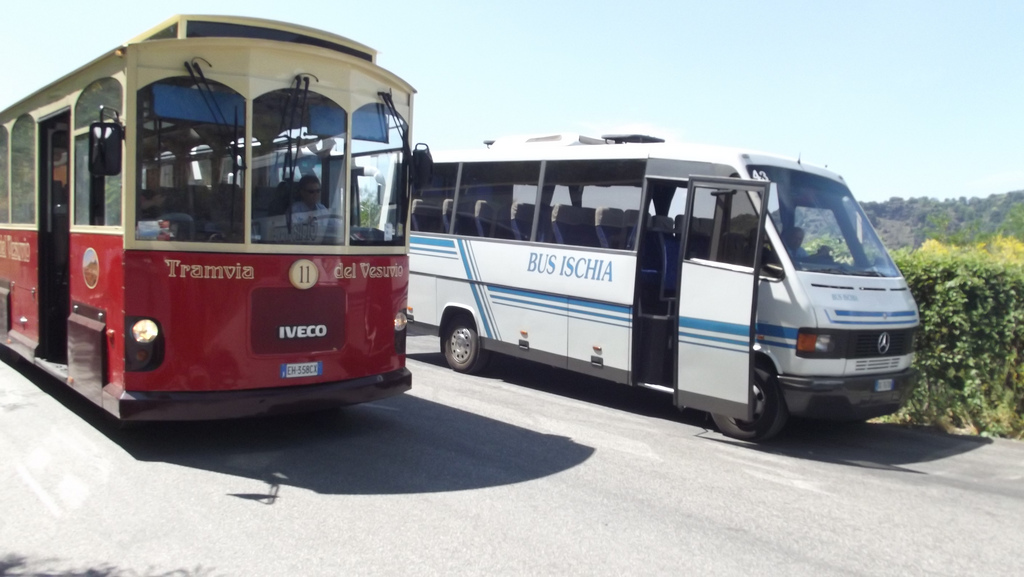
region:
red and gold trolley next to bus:
[0, 16, 419, 427]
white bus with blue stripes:
[400, 129, 926, 440]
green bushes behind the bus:
[891, 240, 1022, 431]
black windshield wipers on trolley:
[174, 60, 409, 237]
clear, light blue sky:
[0, 0, 1019, 197]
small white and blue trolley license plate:
[276, 356, 322, 377]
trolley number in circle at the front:
[289, 257, 321, 287]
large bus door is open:
[627, 172, 771, 410]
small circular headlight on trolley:
[128, 318, 155, 345]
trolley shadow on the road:
[136, 386, 593, 507]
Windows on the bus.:
[408, 43, 842, 436]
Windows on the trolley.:
[44, 36, 498, 400]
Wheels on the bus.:
[423, 276, 664, 469]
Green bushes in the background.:
[729, 119, 1008, 462]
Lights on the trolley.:
[50, 168, 342, 464]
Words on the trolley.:
[119, 219, 222, 350]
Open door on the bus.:
[616, 122, 826, 490]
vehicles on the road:
[40, 13, 957, 565]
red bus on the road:
[36, 0, 492, 464]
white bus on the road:
[451, 69, 1005, 421]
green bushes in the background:
[802, 168, 993, 396]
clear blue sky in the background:
[416, 10, 1021, 198]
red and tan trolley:
[37, 17, 423, 442]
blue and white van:
[463, 103, 865, 416]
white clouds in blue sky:
[472, 47, 536, 104]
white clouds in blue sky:
[698, 37, 766, 111]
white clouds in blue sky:
[903, 116, 986, 186]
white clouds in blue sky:
[799, 50, 889, 133]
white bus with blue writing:
[358, 130, 940, 448]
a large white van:
[405, 146, 918, 431]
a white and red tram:
[3, 12, 419, 439]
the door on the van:
[640, 187, 758, 410]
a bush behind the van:
[885, 244, 1016, 435]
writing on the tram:
[152, 246, 263, 282]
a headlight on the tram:
[130, 316, 163, 345]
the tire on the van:
[446, 318, 482, 367]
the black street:
[0, 342, 1021, 574]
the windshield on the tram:
[151, 79, 407, 244]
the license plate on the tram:
[288, 363, 320, 371]